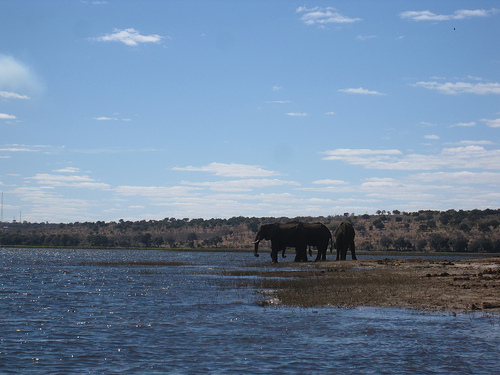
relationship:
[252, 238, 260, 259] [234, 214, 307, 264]
nose of elephant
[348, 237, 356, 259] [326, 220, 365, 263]
leg of elephant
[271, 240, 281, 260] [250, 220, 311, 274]
leg of elephant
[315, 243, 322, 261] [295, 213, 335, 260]
leg of elephant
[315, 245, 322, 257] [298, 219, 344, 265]
leg of elephant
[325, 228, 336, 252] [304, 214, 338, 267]
tail of elephant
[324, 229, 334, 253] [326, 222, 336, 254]
tail of elephant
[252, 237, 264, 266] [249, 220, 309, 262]
trunk of elephant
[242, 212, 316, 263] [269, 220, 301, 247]
body of elephant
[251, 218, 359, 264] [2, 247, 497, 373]
elephant herd by water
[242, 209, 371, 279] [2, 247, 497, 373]
elephant herd by water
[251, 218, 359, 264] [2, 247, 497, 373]
elephant herd beside water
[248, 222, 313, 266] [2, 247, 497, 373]
animal beside water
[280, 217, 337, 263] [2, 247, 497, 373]
elephant near water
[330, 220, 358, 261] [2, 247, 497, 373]
elephant near water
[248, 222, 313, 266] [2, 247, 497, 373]
animal near water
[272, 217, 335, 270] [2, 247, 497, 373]
elephant near water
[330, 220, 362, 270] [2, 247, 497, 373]
elephant near water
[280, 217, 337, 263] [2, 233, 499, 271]
elephant standing on shore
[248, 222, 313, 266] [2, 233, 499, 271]
animal standing on shore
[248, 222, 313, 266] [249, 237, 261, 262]
animal has trunk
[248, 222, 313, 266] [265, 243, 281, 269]
animal has legs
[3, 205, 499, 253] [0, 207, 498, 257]
bushes on hillside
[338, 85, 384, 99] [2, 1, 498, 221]
cloud in sky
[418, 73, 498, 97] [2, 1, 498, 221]
cloud in sky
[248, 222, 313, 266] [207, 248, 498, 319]
animal on bank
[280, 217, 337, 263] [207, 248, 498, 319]
elephant on bank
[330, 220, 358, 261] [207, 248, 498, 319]
elephant on bank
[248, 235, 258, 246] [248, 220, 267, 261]
tusk on face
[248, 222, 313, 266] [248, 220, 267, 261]
animal has face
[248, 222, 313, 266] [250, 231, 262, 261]
animal has trunk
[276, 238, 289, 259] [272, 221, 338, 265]
trunk under elephant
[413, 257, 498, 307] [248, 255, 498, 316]
clumps on sand bar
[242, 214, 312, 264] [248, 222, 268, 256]
animal has trunk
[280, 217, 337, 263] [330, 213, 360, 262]
elephant near animal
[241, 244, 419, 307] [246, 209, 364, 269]
dirt under animals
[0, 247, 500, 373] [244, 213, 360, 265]
water next animals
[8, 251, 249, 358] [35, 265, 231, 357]
water has ripples